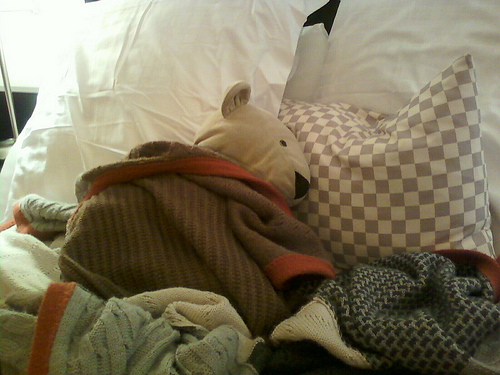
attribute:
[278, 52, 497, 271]
pillow — checkered, tan, cream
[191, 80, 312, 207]
teddy bear — white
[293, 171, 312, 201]
nose — black, triangular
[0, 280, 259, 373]
blanket — green, cable knit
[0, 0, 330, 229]
pillow — large, white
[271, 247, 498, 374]
blanket — two tone, grey, white, knit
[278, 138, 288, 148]
eye — black, button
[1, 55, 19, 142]
bar — silver, metal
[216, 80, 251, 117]
ear — round, gathered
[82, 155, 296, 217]
border — red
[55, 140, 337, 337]
blanket — brown, striped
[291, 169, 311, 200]
nose — black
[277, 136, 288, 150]
eye — black